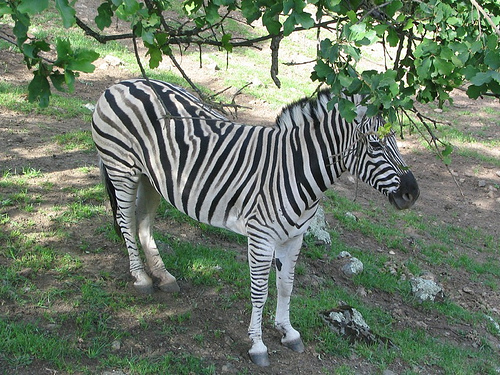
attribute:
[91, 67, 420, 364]
zebra — black, white, striped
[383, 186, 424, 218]
nose — black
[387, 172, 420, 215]
mouth — black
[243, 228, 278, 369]
leg — left front leg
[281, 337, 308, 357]
hoof — left front hoof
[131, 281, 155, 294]
hoof — back right hoof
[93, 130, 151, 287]
leg — back front leg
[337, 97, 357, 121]
leaf — green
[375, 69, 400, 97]
leaf — green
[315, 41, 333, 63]
leaf — green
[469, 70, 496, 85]
leaf — green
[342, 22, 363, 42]
leaf — green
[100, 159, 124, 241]
tail — black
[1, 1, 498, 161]
leaves — green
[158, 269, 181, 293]
hoof — back left hoof